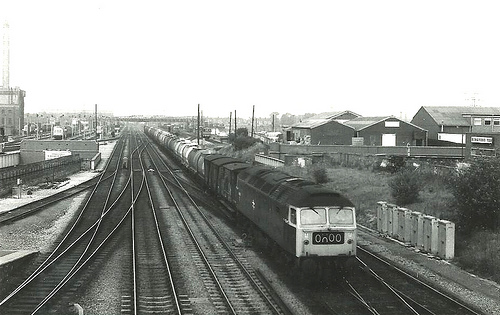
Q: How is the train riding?
A: Tracks.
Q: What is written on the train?
A: 0n00.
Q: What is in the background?
A: Buildings.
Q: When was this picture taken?
A: Daytime.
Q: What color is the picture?
A: Black and White.